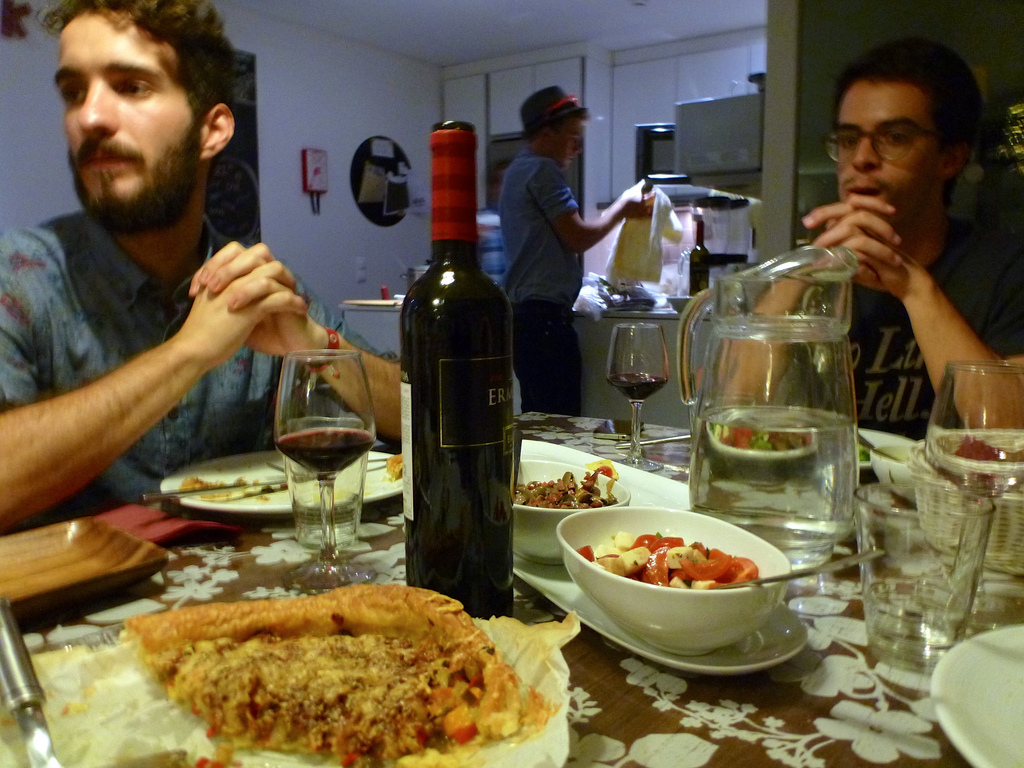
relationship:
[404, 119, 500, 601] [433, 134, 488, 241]
bottle with top